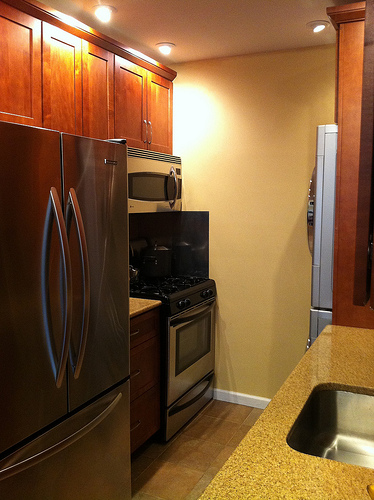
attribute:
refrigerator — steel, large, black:
[0, 122, 130, 495]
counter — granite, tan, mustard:
[211, 326, 373, 499]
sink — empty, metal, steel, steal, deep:
[293, 380, 373, 472]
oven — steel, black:
[146, 270, 226, 430]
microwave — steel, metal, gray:
[124, 149, 186, 214]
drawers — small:
[125, 317, 161, 445]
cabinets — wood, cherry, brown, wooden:
[2, 12, 184, 149]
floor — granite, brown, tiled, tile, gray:
[137, 402, 266, 499]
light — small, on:
[91, 5, 120, 25]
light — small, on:
[155, 38, 176, 56]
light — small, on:
[309, 21, 328, 34]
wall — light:
[175, 60, 317, 387]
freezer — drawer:
[4, 380, 147, 498]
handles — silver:
[142, 118, 156, 143]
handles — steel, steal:
[46, 186, 86, 392]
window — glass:
[178, 323, 212, 365]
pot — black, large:
[140, 245, 169, 276]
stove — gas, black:
[135, 273, 200, 296]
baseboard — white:
[213, 384, 273, 413]